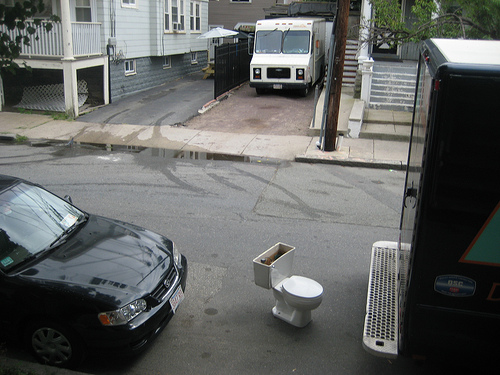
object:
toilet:
[250, 241, 325, 328]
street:
[0, 137, 408, 375]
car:
[0, 175, 190, 372]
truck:
[248, 15, 325, 96]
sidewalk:
[0, 112, 409, 165]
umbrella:
[195, 23, 238, 41]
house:
[0, 0, 209, 120]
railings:
[213, 37, 250, 99]